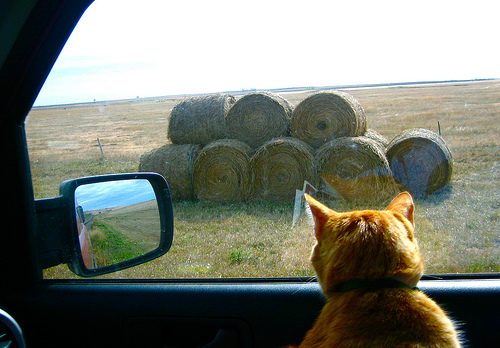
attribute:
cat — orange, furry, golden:
[301, 192, 467, 346]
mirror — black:
[61, 173, 174, 276]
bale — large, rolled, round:
[290, 90, 366, 149]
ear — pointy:
[304, 191, 337, 242]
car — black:
[0, 1, 498, 344]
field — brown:
[24, 80, 498, 277]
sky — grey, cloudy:
[36, 1, 496, 107]